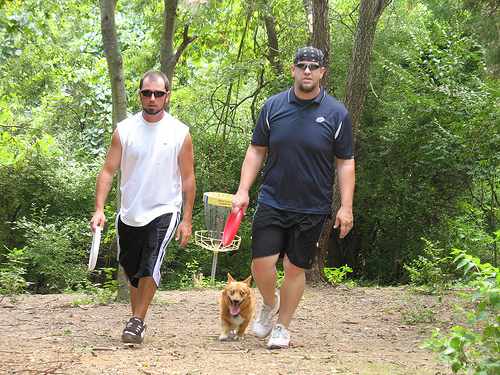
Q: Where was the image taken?
A: It was taken at the forest.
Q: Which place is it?
A: It is a forest.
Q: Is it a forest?
A: Yes, it is a forest.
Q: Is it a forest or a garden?
A: It is a forest.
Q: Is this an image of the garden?
A: No, the picture is showing the forest.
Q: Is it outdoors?
A: Yes, it is outdoors.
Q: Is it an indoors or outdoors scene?
A: It is outdoors.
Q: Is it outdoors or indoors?
A: It is outdoors.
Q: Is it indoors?
A: No, it is outdoors.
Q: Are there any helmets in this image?
A: No, there are no helmets.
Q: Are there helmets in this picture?
A: No, there are no helmets.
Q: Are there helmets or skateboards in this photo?
A: No, there are no helmets or skateboards.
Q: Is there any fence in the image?
A: No, there are no fences.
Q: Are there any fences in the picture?
A: No, there are no fences.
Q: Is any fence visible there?
A: No, there are no fences.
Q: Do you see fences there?
A: No, there are no fences.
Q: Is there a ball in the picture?
A: No, there are no balls.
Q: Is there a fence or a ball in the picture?
A: No, there are no balls or fences.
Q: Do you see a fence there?
A: No, there are no fences.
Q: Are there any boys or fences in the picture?
A: No, there are no fences or boys.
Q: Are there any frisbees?
A: Yes, there is a frisbee.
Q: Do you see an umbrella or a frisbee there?
A: Yes, there is a frisbee.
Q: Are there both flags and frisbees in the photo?
A: No, there is a frisbee but no flags.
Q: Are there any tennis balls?
A: No, there are no tennis balls.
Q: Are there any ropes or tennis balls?
A: No, there are no tennis balls or ropes.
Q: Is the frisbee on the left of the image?
A: Yes, the frisbee is on the left of the image.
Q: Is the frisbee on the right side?
A: No, the frisbee is on the left of the image.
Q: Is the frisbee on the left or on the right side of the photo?
A: The frisbee is on the left of the image.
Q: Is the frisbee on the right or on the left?
A: The frisbee is on the left of the image.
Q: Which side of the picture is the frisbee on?
A: The frisbee is on the left of the image.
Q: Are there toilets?
A: No, there are no toilets.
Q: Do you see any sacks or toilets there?
A: No, there are no toilets or sacks.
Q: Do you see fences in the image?
A: No, there are no fences.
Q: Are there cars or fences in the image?
A: No, there are no fences or cars.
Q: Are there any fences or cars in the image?
A: No, there are no fences or cars.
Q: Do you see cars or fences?
A: No, there are no fences or cars.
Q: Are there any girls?
A: No, there are no girls.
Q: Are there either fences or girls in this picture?
A: No, there are no girls or fences.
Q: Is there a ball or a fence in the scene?
A: No, there are no fences or balls.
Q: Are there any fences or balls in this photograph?
A: No, there are no fences or balls.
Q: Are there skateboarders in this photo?
A: No, there are no skateboarders.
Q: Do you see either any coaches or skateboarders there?
A: No, there are no skateboarders or coaches.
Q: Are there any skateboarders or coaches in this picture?
A: No, there are no skateboarders or coaches.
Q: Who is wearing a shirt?
A: The guy is wearing a shirt.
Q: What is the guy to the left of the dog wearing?
A: The guy is wearing a shirt.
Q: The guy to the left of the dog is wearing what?
A: The guy is wearing a shirt.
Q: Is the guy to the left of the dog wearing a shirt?
A: Yes, the guy is wearing a shirt.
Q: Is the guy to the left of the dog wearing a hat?
A: No, the guy is wearing a shirt.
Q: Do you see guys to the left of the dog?
A: Yes, there is a guy to the left of the dog.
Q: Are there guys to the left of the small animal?
A: Yes, there is a guy to the left of the dog.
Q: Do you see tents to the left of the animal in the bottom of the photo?
A: No, there is a guy to the left of the dog.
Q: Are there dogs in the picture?
A: Yes, there is a dog.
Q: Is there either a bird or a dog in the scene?
A: Yes, there is a dog.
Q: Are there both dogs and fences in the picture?
A: No, there is a dog but no fences.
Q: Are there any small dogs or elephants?
A: Yes, there is a small dog.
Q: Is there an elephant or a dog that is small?
A: Yes, the dog is small.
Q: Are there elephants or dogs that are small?
A: Yes, the dog is small.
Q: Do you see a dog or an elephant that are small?
A: Yes, the dog is small.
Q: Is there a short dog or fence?
A: Yes, there is a short dog.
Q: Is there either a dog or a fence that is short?
A: Yes, the dog is short.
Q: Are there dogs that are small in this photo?
A: Yes, there is a small dog.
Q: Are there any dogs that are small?
A: Yes, there is a dog that is small.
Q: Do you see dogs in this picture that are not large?
A: Yes, there is a small dog.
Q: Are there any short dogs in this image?
A: Yes, there is a short dog.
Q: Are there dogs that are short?
A: Yes, there is a dog that is short.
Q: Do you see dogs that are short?
A: Yes, there is a dog that is short.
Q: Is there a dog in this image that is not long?
A: Yes, there is a short dog.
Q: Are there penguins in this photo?
A: No, there are no penguins.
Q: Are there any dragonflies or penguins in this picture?
A: No, there are no penguins or dragonflies.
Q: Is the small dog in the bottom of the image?
A: Yes, the dog is in the bottom of the image.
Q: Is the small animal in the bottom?
A: Yes, the dog is in the bottom of the image.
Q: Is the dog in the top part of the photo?
A: No, the dog is in the bottom of the image.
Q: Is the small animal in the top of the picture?
A: No, the dog is in the bottom of the image.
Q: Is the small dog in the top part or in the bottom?
A: The dog is in the bottom of the image.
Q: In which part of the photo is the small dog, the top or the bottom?
A: The dog is in the bottom of the image.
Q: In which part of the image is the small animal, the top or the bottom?
A: The dog is in the bottom of the image.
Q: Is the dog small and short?
A: Yes, the dog is small and short.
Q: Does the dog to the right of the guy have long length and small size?
A: No, the dog is small but short.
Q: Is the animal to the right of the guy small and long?
A: No, the dog is small but short.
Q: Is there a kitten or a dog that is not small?
A: No, there is a dog but it is small.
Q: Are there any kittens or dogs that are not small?
A: No, there is a dog but it is small.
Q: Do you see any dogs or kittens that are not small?
A: No, there is a dog but it is small.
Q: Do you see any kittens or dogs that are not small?
A: No, there is a dog but it is small.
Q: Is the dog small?
A: Yes, the dog is small.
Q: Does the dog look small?
A: Yes, the dog is small.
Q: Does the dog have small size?
A: Yes, the dog is small.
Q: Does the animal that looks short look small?
A: Yes, the dog is small.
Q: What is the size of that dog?
A: The dog is small.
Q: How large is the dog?
A: The dog is small.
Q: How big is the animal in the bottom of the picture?
A: The dog is small.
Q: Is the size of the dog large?
A: No, the dog is small.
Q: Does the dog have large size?
A: No, the dog is small.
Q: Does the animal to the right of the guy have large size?
A: No, the dog is small.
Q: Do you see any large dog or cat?
A: No, there is a dog but it is small.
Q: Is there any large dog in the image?
A: No, there is a dog but it is small.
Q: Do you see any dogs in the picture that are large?
A: No, there is a dog but it is small.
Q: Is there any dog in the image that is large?
A: No, there is a dog but it is small.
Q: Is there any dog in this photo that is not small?
A: No, there is a dog but it is small.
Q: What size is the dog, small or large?
A: The dog is small.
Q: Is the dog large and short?
A: No, the dog is short but small.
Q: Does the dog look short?
A: Yes, the dog is short.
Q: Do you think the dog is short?
A: Yes, the dog is short.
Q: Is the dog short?
A: Yes, the dog is short.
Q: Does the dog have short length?
A: Yes, the dog is short.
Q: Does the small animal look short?
A: Yes, the dog is short.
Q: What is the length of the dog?
A: The dog is short.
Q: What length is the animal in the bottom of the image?
A: The dog is short.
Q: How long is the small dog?
A: The dog is short.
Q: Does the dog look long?
A: No, the dog is short.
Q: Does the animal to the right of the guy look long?
A: No, the dog is short.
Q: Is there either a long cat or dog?
A: No, there is a dog but it is short.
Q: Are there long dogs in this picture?
A: No, there is a dog but it is short.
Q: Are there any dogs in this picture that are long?
A: No, there is a dog but it is short.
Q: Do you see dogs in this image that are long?
A: No, there is a dog but it is short.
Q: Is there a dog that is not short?
A: No, there is a dog but it is short.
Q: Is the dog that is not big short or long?
A: The dog is short.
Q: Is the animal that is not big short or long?
A: The dog is short.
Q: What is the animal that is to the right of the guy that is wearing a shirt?
A: The animal is a dog.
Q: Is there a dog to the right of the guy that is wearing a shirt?
A: Yes, there is a dog to the right of the guy.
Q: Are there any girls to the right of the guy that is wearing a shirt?
A: No, there is a dog to the right of the guy.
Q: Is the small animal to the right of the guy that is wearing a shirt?
A: Yes, the dog is to the right of the guy.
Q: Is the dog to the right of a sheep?
A: No, the dog is to the right of the guy.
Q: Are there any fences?
A: No, there are no fences.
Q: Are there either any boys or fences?
A: No, there are no fences or boys.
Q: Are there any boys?
A: No, there are no boys.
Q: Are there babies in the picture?
A: No, there are no babies.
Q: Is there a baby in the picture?
A: No, there are no babies.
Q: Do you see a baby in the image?
A: No, there are no babies.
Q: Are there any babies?
A: No, there are no babies.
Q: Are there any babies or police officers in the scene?
A: No, there are no babies or police officers.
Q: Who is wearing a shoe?
A: The guy is wearing a shoe.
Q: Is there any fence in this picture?
A: No, there are no fences.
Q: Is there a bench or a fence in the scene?
A: No, there are no fences or benches.